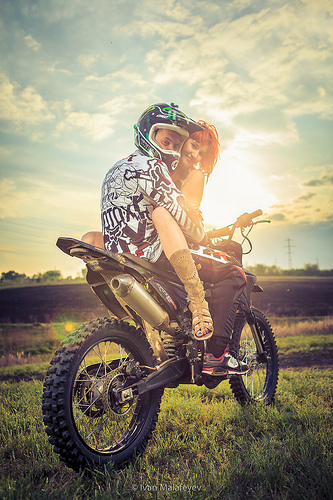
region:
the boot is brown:
[173, 257, 205, 303]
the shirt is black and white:
[111, 172, 138, 214]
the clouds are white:
[176, 48, 205, 73]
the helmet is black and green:
[131, 105, 195, 167]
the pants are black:
[221, 269, 234, 313]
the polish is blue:
[195, 329, 207, 339]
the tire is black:
[49, 358, 72, 381]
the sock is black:
[209, 334, 223, 352]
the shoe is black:
[201, 346, 249, 385]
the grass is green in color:
[182, 425, 231, 466]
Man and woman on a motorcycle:
[69, 147, 237, 322]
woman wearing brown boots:
[165, 222, 206, 344]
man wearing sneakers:
[189, 328, 257, 392]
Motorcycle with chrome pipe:
[112, 280, 184, 341]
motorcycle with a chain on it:
[88, 358, 166, 429]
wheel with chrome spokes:
[70, 336, 157, 449]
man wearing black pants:
[182, 255, 251, 330]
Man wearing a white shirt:
[92, 135, 190, 250]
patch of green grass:
[290, 437, 306, 451]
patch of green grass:
[199, 448, 215, 467]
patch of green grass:
[33, 453, 47, 468]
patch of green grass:
[20, 403, 31, 417]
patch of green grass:
[305, 382, 320, 398]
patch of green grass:
[290, 464, 312, 488]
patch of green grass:
[290, 378, 300, 395]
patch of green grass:
[203, 432, 219, 448]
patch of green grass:
[213, 413, 229, 430]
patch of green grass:
[307, 373, 316, 386]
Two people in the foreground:
[91, 95, 262, 379]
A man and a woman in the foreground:
[76, 87, 254, 383]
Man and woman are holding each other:
[67, 95, 264, 383]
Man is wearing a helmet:
[124, 97, 210, 176]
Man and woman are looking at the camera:
[126, 94, 222, 182]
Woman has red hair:
[181, 110, 226, 185]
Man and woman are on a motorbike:
[31, 187, 302, 478]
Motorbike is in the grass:
[41, 371, 318, 489]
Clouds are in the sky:
[2, 1, 332, 260]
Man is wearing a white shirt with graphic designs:
[96, 145, 207, 264]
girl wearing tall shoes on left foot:
[165, 243, 226, 343]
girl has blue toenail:
[195, 323, 206, 336]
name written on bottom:
[110, 464, 209, 491]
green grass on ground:
[180, 412, 301, 480]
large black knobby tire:
[44, 317, 177, 448]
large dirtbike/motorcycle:
[74, 219, 305, 409]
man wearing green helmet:
[124, 90, 217, 187]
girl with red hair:
[185, 113, 218, 173]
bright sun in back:
[190, 134, 292, 216]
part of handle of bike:
[220, 198, 273, 274]